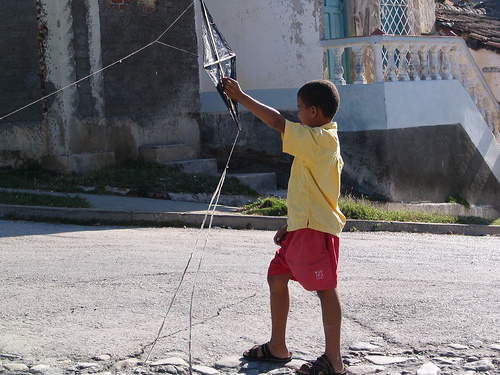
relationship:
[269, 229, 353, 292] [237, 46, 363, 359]
red shorts on body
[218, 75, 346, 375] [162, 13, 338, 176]
boy holding kite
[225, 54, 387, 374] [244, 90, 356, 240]
boy wearing shirt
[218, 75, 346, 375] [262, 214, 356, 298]
boy wearing shorts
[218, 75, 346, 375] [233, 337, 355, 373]
boy wearing sandals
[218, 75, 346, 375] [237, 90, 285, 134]
boy has arm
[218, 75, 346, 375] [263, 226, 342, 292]
boy in red shorts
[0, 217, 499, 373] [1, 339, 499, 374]
ground made of broken cement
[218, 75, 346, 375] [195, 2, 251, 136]
boy holding kite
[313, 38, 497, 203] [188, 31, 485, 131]
staircase in background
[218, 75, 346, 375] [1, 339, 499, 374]
boy wearing broken cement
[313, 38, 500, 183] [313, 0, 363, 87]
staircase in front of door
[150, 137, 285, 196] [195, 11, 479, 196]
steps of building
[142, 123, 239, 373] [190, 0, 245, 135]
string on kite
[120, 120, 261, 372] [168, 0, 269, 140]
tail on bottom of kite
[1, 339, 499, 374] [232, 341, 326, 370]
broken cement on feet